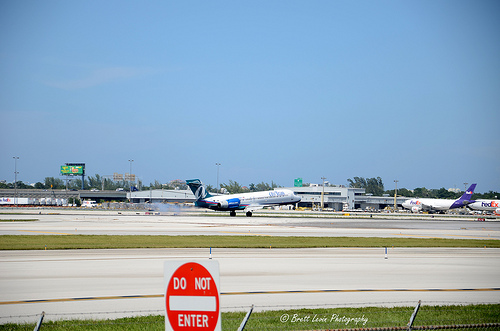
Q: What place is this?
A: It is an airport.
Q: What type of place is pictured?
A: It is an airport.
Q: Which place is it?
A: It is an airport.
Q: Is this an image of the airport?
A: Yes, it is showing the airport.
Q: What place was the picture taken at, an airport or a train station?
A: It was taken at an airport.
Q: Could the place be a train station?
A: No, it is an airport.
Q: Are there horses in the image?
A: No, there are no horses.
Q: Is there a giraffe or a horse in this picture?
A: No, there are no horses or giraffes.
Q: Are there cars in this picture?
A: No, there are no cars.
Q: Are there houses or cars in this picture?
A: No, there are no cars or houses.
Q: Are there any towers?
A: No, there are no towers.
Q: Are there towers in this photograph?
A: No, there are no towers.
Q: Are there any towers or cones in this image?
A: No, there are no towers or cones.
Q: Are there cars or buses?
A: No, there are no cars or buses.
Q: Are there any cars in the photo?
A: No, there are no cars.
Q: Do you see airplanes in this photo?
A: Yes, there is an airplane.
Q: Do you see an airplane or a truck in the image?
A: Yes, there is an airplane.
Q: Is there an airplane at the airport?
A: Yes, there is an airplane at the airport.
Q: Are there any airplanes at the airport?
A: Yes, there is an airplane at the airport.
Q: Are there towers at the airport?
A: No, there is an airplane at the airport.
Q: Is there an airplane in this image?
A: Yes, there is an airplane.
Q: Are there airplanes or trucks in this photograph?
A: Yes, there is an airplane.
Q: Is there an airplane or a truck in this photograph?
A: Yes, there is an airplane.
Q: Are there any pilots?
A: No, there are no pilots.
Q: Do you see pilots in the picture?
A: No, there are no pilots.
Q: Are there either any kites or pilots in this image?
A: No, there are no pilots or kites.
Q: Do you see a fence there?
A: Yes, there is a fence.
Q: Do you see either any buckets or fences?
A: Yes, there is a fence.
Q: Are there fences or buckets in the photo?
A: Yes, there is a fence.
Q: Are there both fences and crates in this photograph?
A: No, there is a fence but no crates.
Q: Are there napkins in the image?
A: No, there are no napkins.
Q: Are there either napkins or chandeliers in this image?
A: No, there are no napkins or chandeliers.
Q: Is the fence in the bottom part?
A: Yes, the fence is in the bottom of the image.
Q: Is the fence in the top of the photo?
A: No, the fence is in the bottom of the image.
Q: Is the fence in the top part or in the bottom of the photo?
A: The fence is in the bottom of the image.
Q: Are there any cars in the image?
A: No, there are no cars.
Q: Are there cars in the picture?
A: No, there are no cars.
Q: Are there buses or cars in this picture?
A: No, there are no cars or buses.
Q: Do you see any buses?
A: No, there are no buses.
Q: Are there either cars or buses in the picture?
A: No, there are no buses or cars.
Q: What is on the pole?
A: The sign is on the pole.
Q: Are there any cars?
A: No, there are no cars.